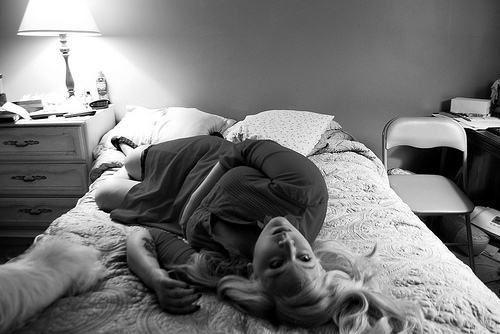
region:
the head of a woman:
[243, 190, 355, 309]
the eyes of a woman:
[243, 243, 338, 295]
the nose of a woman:
[271, 231, 296, 250]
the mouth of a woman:
[264, 213, 297, 247]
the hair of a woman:
[228, 240, 369, 322]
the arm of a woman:
[88, 186, 197, 318]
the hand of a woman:
[151, 262, 228, 318]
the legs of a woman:
[93, 112, 226, 229]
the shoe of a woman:
[104, 120, 155, 182]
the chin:
[246, 186, 328, 242]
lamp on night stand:
[18, 0, 101, 99]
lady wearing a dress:
[96, 138, 423, 333]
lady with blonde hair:
[96, 136, 417, 331]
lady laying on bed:
[93, 135, 422, 332]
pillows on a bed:
[105, 103, 334, 158]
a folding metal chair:
[381, 115, 475, 264]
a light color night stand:
[1, 97, 114, 236]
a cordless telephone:
[94, 72, 109, 104]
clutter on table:
[448, 95, 498, 138]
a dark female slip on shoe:
[110, 135, 135, 149]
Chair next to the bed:
[377, 109, 475, 260]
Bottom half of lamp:
[55, 33, 76, 100]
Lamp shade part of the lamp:
[11, 0, 104, 45]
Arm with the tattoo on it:
[127, 227, 164, 275]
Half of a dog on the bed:
[0, 228, 106, 327]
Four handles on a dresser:
[3, 132, 53, 223]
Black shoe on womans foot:
[107, 132, 138, 150]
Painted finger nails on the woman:
[174, 276, 206, 320]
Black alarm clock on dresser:
[88, 97, 110, 110]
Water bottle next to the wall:
[90, 66, 111, 97]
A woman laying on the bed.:
[99, 130, 349, 315]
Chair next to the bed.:
[373, 97, 460, 227]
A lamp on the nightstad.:
[31, 4, 93, 116]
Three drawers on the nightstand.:
[5, 126, 90, 230]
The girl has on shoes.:
[113, 126, 168, 152]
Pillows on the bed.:
[125, 98, 287, 149]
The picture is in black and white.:
[47, 11, 477, 331]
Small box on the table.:
[456, 73, 499, 110]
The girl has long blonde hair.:
[323, 242, 416, 314]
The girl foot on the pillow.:
[97, 129, 141, 169]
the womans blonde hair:
[294, 298, 432, 332]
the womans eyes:
[258, 252, 327, 269]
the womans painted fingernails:
[176, 278, 209, 318]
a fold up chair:
[375, 113, 480, 238]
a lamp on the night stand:
[11, 0, 91, 107]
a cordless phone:
[87, 68, 112, 97]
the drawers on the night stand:
[3, 132, 83, 236]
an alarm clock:
[87, 100, 117, 109]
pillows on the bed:
[248, 112, 355, 146]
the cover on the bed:
[318, 144, 383, 241]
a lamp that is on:
[7, 0, 115, 120]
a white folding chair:
[379, 109, 481, 253]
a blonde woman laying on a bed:
[94, 122, 408, 332]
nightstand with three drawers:
[0, 92, 113, 251]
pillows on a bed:
[91, 92, 352, 174]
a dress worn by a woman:
[110, 132, 335, 279]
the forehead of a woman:
[271, 264, 318, 294]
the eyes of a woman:
[262, 246, 317, 271]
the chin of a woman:
[269, 211, 290, 228]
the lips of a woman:
[264, 226, 297, 236]